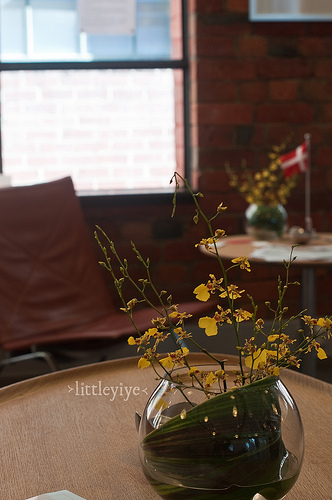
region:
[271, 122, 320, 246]
red flag with a white cross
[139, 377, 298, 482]
green leaves in a fishbowl vase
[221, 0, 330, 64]
grate in a brick wall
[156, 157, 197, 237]
broken tip of a flower stem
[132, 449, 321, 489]
water in the bottom of a vase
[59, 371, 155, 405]
littleyiye photographers stamp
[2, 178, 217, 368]
brown leather chair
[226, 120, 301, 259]
blurry yellow flowers in a vase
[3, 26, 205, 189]
bright sun in the window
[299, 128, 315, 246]
small table top flagpole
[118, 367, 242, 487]
A flower vase is visible.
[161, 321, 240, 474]
A flower vase is visible.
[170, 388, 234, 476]
A flower vase is visible.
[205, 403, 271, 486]
A flower vase is visible.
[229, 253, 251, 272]
yellow bloom on plant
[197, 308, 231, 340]
yellow bloom on plant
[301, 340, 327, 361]
yellow bloom on plant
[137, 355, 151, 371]
yellow bloom on plant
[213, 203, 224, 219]
yellow bloom on plant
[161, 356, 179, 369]
yellow bloom on plant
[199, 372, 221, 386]
yellow bloom on plant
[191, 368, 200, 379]
yellow bloom on plant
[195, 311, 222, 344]
yellow flower hanging off plant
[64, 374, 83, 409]
the letter L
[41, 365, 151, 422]
word in white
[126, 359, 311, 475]
clear bowl on the table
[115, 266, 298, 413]
flowers in a bowl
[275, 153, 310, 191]
flag in the background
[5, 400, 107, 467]
brown table next to bowl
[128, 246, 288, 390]
many yellow flowers in bowl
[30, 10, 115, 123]
window in the background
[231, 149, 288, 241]
blurry flowers in a bowl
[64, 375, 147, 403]
white watermark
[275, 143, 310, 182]
red and white flag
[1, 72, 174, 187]
brick wall with light streaming on it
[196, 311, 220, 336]
tiny yellow petals shaped like a heart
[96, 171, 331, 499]
round fishbowl holding a plant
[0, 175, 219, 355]
thin brown chair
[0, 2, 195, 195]
half open window letting the light in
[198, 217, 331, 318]
small, round wooden table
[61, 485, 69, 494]
sharp white corner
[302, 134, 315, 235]
tall and skinny flagpole